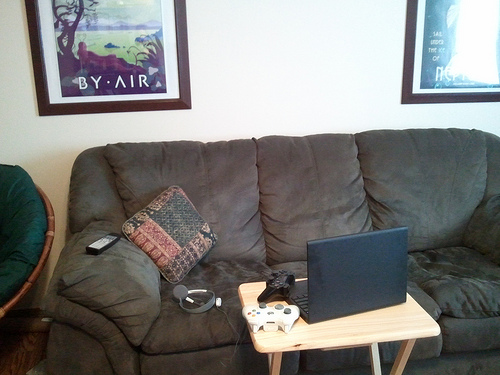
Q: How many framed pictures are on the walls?
A: 2.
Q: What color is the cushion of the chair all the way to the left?
A: Green.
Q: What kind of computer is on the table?
A: Laptop.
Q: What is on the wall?
A: Two pictures.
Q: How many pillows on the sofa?
A: One.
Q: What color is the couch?
A: Brown.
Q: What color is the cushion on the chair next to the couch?
A: Green.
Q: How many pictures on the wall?
A: Two.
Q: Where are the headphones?
A: On the sofa.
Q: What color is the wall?
A: White.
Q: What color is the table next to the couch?
A: Brown.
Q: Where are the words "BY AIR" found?
A: On the picture behind the sofa.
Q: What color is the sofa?
A: Grey.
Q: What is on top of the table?
A: Computer.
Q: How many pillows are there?
A: One.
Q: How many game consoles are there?
A: Two.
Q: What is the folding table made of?
A: Wood.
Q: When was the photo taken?
A: Daytime.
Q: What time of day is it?
A: Afternoon.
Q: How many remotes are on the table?
A: Two.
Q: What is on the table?
A: Laptop.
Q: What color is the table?
A: Brown.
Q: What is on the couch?
A: A pillow and headset.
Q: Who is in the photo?
A: No one.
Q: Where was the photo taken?
A: In the living room.